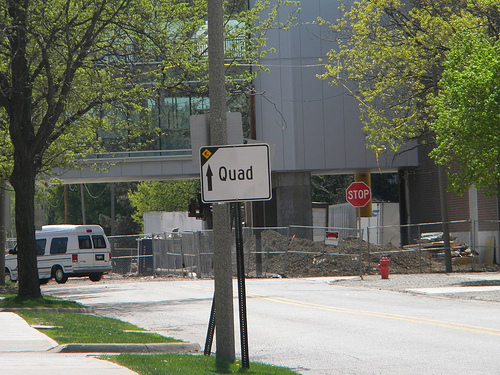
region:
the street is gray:
[321, 323, 402, 371]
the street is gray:
[301, 317, 362, 353]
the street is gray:
[292, 332, 340, 356]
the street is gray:
[270, 306, 337, 353]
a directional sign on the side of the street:
[195, 141, 276, 371]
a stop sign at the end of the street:
[341, 176, 373, 281]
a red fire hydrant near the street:
[375, 250, 393, 281]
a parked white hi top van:
[2, 220, 112, 285]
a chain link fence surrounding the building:
[22, 221, 497, 276]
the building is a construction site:
[23, 58, 489, 273]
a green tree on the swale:
[2, 0, 289, 310]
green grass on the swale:
[5, 291, 285, 372]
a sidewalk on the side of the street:
[1, 307, 141, 372]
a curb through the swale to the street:
[56, 332, 203, 360]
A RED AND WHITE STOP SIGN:
[336, 166, 380, 243]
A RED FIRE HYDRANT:
[366, 253, 420, 288]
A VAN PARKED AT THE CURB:
[13, 221, 120, 283]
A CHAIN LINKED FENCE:
[265, 213, 367, 286]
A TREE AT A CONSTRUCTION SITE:
[319, 1, 498, 256]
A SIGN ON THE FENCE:
[316, 221, 353, 254]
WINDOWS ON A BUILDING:
[94, 85, 230, 160]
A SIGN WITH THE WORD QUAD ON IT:
[191, 137, 291, 222]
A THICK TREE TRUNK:
[5, 157, 57, 312]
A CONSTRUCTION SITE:
[162, 201, 479, 283]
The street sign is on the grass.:
[195, 138, 291, 372]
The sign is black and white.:
[187, 137, 279, 211]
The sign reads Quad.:
[193, 140, 275, 207]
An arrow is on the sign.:
[200, 160, 216, 198]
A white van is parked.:
[3, 211, 117, 288]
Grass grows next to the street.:
[26, 292, 297, 373]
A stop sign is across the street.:
[327, 172, 384, 283]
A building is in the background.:
[44, 2, 435, 274]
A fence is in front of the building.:
[97, 191, 457, 283]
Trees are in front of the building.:
[0, 2, 497, 303]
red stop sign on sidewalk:
[341, 177, 376, 211]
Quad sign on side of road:
[187, 137, 300, 219]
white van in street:
[7, 214, 114, 286]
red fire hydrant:
[366, 249, 398, 290]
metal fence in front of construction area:
[241, 214, 475, 283]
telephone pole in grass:
[201, 14, 238, 372]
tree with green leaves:
[4, 7, 156, 307]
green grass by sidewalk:
[30, 307, 162, 357]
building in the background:
[223, 6, 434, 176]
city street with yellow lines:
[275, 296, 485, 358]